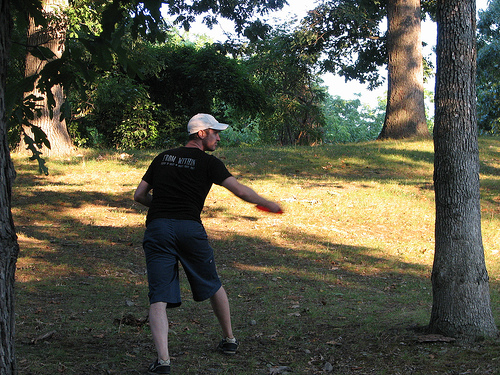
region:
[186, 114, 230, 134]
white baseball cap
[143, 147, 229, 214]
black t-shirt with a print in white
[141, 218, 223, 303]
knee length navy shorts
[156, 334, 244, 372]
dark sneakers with anl\kle socks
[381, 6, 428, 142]
sun dappled tree trunk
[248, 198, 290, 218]
man about to throw a red frisbee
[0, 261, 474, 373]
dried leaves scattered on the ground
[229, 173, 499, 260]
a sunny area of the ground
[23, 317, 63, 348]
a stick on ground behind the man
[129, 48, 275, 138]
a large green leafed shrub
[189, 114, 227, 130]
a hat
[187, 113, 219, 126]
the hat is white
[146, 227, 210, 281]
a man wearing blue shorts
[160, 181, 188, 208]
a black shirt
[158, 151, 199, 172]
writing on the shirt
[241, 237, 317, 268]
a shadow on the grass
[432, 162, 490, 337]
the tree trunk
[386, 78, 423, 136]
shadow on the tree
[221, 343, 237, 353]
a shoe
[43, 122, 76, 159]
sunlight on the tree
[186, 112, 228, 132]
white hat on man's head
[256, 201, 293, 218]
frisbee in man's hand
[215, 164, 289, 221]
the man's right arm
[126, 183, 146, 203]
the man's left elbow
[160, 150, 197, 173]
name on back of shirt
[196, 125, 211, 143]
the right ear of the man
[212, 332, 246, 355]
gym shoe on man's right foot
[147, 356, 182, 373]
shoe on man's left foot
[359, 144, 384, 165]
green grass on the ground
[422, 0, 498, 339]
bark of the tree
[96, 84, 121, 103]
green leaf on tree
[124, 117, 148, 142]
green leaf on tree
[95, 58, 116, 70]
green leaf on tree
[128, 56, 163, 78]
green leaf on tree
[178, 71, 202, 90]
green leaf on tree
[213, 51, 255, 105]
green leaf on tree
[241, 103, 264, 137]
green leaf on tree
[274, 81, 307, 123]
green leaf on tree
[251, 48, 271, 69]
green leaf on tree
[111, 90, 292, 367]
Man playing with a frisbee.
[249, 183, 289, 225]
Frisbee in man's right hand.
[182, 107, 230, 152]
Man wearing a white hat.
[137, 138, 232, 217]
Man wearing a black shirt.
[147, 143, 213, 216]
White writing on black shirt.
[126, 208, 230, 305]
A pair of grey shorts.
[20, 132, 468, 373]
Leaves scattered on ground.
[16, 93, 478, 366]
Shadows of trees on the ground.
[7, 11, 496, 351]
Three tall tree trunks.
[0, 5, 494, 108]
Green leaves on the trees.